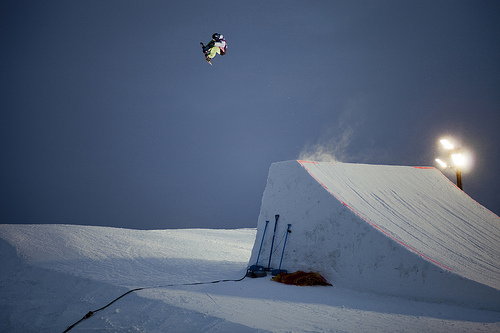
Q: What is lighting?
A: The lights.